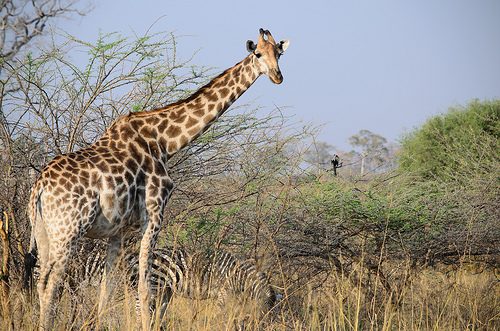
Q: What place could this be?
A: It is a field.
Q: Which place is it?
A: It is a field.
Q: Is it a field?
A: Yes, it is a field.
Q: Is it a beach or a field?
A: It is a field.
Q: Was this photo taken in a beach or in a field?
A: It was taken at a field.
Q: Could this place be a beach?
A: No, it is a field.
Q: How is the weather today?
A: It is clear.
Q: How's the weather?
A: It is clear.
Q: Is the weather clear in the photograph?
A: Yes, it is clear.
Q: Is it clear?
A: Yes, it is clear.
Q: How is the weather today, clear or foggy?
A: It is clear.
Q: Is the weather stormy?
A: No, it is clear.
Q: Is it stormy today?
A: No, it is clear.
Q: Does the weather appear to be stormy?
A: No, it is clear.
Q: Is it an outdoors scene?
A: Yes, it is outdoors.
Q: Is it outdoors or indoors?
A: It is outdoors.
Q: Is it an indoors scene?
A: No, it is outdoors.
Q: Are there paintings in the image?
A: No, there are no paintings.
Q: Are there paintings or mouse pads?
A: No, there are no paintings or mouse pads.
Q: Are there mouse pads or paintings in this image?
A: No, there are no paintings or mouse pads.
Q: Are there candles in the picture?
A: No, there are no candles.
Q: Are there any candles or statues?
A: No, there are no candles or statues.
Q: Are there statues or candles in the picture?
A: No, there are no candles or statues.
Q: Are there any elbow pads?
A: No, there are no elbow pads.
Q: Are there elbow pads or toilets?
A: No, there are no elbow pads or toilets.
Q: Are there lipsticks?
A: No, there are no lipsticks.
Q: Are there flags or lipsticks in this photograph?
A: No, there are no lipsticks or flags.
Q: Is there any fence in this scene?
A: No, there are no fences.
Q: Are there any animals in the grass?
A: Yes, there are animals in the grass.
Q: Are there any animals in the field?
A: Yes, there are animals in the field.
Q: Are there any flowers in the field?
A: No, there are animals in the field.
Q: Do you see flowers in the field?
A: No, there are animals in the field.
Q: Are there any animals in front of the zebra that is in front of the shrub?
A: Yes, there are animals in front of the zebra.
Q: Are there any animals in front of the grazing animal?
A: Yes, there are animals in front of the zebra.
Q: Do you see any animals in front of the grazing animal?
A: Yes, there are animals in front of the zebra.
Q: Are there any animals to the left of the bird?
A: Yes, there are animals to the left of the bird.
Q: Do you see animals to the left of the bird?
A: Yes, there are animals to the left of the bird.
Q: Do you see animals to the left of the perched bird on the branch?
A: Yes, there are animals to the left of the bird.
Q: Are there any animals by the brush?
A: Yes, there are animals by the brush.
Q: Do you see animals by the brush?
A: Yes, there are animals by the brush.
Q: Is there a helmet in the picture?
A: No, there are no helmets.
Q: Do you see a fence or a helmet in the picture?
A: No, there are no helmets or fences.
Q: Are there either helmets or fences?
A: No, there are no helmets or fences.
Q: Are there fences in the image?
A: No, there are no fences.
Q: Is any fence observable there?
A: No, there are no fences.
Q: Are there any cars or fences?
A: No, there are no fences or cars.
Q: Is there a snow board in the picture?
A: No, there are no snowboards.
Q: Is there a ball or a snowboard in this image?
A: No, there are no snowboards or balls.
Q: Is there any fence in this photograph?
A: No, there are no fences.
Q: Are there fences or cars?
A: No, there are no fences or cars.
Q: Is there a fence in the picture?
A: No, there are no fences.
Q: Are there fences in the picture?
A: No, there are no fences.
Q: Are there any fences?
A: No, there are no fences.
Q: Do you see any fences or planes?
A: No, there are no fences or planes.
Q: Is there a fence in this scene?
A: No, there are no fences.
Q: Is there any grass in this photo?
A: Yes, there is grass.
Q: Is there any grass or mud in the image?
A: Yes, there is grass.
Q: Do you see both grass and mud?
A: No, there is grass but no mud.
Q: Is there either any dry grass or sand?
A: Yes, there is dry grass.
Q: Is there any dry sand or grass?
A: Yes, there is dry grass.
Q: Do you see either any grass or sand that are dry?
A: Yes, the grass is dry.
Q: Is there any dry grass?
A: Yes, there is dry grass.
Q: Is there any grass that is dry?
A: Yes, there is grass that is dry.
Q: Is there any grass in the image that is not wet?
A: Yes, there is dry grass.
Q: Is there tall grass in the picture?
A: Yes, there is tall grass.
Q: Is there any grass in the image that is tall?
A: Yes, there is grass that is tall.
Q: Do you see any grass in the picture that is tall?
A: Yes, there is grass that is tall.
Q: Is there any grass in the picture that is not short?
A: Yes, there is tall grass.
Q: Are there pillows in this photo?
A: No, there are no pillows.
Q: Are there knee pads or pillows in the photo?
A: No, there are no pillows or knee pads.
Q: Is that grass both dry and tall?
A: Yes, the grass is dry and tall.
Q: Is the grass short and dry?
A: No, the grass is dry but tall.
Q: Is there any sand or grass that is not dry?
A: No, there is grass but it is dry.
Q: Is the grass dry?
A: Yes, the grass is dry.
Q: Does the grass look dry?
A: Yes, the grass is dry.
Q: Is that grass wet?
A: No, the grass is dry.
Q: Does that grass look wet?
A: No, the grass is dry.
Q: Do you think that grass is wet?
A: No, the grass is dry.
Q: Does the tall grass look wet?
A: No, the grass is dry.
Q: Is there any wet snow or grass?
A: No, there is grass but it is dry.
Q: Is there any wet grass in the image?
A: No, there is grass but it is dry.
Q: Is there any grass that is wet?
A: No, there is grass but it is dry.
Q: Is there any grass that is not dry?
A: No, there is grass but it is dry.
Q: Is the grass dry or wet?
A: The grass is dry.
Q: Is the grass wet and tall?
A: No, the grass is tall but dry.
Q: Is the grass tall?
A: Yes, the grass is tall.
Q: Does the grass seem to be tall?
A: Yes, the grass is tall.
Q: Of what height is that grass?
A: The grass is tall.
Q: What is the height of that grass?
A: The grass is tall.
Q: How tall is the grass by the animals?
A: The grass is tall.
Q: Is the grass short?
A: No, the grass is tall.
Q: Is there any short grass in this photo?
A: No, there is grass but it is tall.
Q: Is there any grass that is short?
A: No, there is grass but it is tall.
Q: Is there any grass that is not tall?
A: No, there is grass but it is tall.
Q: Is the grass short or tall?
A: The grass is tall.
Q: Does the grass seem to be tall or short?
A: The grass is tall.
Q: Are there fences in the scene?
A: No, there are no fences.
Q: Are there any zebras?
A: Yes, there is a zebra.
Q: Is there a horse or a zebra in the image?
A: Yes, there is a zebra.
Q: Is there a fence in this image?
A: No, there are no fences.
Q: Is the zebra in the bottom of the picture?
A: Yes, the zebra is in the bottom of the image.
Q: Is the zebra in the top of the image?
A: No, the zebra is in the bottom of the image.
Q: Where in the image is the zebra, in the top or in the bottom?
A: The zebra is in the bottom of the image.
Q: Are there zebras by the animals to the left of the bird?
A: Yes, there is a zebra by the animals.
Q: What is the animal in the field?
A: The animal is a zebra.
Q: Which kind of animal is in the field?
A: The animal is a zebra.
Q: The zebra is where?
A: The zebra is in the field.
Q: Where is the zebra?
A: The zebra is in the field.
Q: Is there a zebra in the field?
A: Yes, there is a zebra in the field.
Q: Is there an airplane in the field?
A: No, there is a zebra in the field.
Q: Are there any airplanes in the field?
A: No, there is a zebra in the field.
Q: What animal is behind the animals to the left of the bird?
A: The animal is a zebra.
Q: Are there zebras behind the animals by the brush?
A: Yes, there is a zebra behind the animals.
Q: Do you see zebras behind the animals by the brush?
A: Yes, there is a zebra behind the animals.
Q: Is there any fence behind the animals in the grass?
A: No, there is a zebra behind the animals.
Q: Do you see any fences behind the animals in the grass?
A: No, there is a zebra behind the animals.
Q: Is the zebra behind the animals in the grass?
A: Yes, the zebra is behind the animals.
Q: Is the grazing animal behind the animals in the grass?
A: Yes, the zebra is behind the animals.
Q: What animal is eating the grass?
A: The zebra is eating the grass.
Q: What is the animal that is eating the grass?
A: The animal is a zebra.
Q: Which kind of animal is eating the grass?
A: The animal is a zebra.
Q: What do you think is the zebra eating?
A: The zebra is eating grass.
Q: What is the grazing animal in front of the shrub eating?
A: The zebra is eating grass.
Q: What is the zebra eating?
A: The zebra is eating grass.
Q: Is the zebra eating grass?
A: Yes, the zebra is eating grass.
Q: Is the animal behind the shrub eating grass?
A: Yes, the zebra is eating grass.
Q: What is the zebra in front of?
A: The zebra is in front of the bush.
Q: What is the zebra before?
A: The zebra is in front of the bush.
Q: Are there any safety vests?
A: No, there are no safety vests.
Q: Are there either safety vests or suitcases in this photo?
A: No, there are no safety vests or suitcases.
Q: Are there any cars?
A: No, there are no cars.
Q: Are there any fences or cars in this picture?
A: No, there are no cars or fences.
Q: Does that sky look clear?
A: Yes, the sky is clear.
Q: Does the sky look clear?
A: Yes, the sky is clear.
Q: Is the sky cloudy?
A: No, the sky is clear.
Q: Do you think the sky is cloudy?
A: No, the sky is clear.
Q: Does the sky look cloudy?
A: No, the sky is clear.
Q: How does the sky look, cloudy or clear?
A: The sky is clear.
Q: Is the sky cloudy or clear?
A: The sky is clear.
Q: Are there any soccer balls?
A: No, there are no soccer balls.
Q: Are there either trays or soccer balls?
A: No, there are no soccer balls or trays.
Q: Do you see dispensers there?
A: No, there are no dispensers.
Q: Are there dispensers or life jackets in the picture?
A: No, there are no dispensers or life jackets.